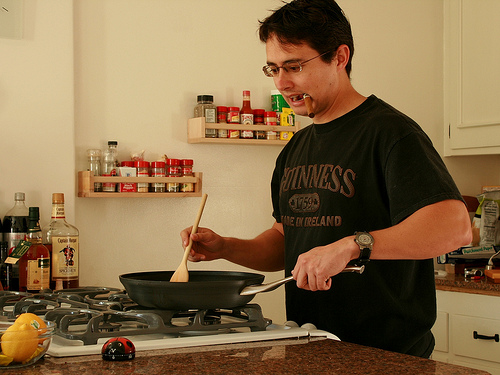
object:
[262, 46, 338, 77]
eyeglasses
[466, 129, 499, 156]
ground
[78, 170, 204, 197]
rack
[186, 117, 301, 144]
spice rack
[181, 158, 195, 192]
spices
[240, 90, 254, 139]
spices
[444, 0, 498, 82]
wall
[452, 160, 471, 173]
ground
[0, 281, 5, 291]
counter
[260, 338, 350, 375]
counter top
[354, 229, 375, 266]
watch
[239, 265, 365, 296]
handle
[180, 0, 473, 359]
man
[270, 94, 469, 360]
shirt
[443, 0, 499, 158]
cabinets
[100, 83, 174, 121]
wall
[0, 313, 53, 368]
bowl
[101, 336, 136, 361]
ladybug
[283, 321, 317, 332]
gas range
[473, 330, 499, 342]
handle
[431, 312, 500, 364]
cabinet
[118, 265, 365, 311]
frying pan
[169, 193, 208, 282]
spoon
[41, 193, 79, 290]
bottle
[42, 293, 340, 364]
range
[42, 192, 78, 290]
liquor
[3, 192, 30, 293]
bottle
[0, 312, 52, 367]
lemons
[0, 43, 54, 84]
wall